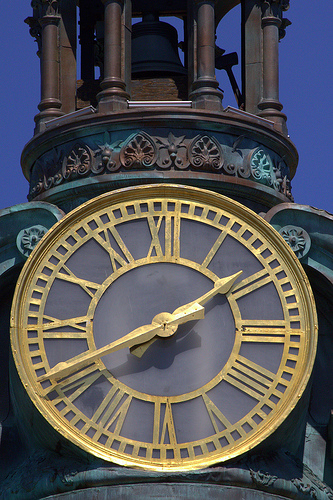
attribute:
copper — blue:
[23, 107, 302, 206]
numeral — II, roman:
[249, 251, 302, 301]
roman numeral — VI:
[139, 396, 182, 448]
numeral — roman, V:
[197, 380, 245, 440]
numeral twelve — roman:
[142, 210, 181, 265]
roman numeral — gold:
[142, 212, 184, 260]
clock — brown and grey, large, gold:
[8, 160, 323, 488]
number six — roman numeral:
[149, 394, 187, 452]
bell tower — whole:
[7, 6, 331, 488]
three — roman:
[237, 317, 289, 343]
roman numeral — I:
[200, 228, 229, 266]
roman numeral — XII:
[144, 214, 182, 258]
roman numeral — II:
[231, 265, 271, 301]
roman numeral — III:
[238, 319, 285, 343]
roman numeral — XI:
[97, 225, 132, 270]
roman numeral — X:
[59, 265, 102, 296]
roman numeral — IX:
[43, 312, 90, 342]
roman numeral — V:
[227, 357, 280, 398]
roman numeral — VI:
[200, 392, 229, 430]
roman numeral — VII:
[95, 385, 134, 431]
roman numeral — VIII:
[51, 359, 101, 398]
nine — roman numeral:
[38, 312, 90, 341]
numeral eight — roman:
[48, 349, 105, 403]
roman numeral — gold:
[149, 397, 179, 449]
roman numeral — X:
[51, 254, 101, 300]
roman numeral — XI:
[89, 211, 139, 274]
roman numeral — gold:
[188, 214, 238, 269]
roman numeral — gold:
[221, 265, 272, 303]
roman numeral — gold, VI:
[148, 392, 183, 465]